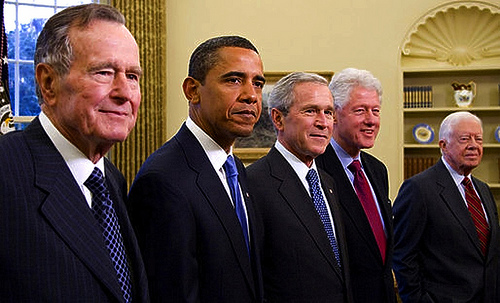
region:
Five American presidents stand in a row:
[2, 15, 467, 231]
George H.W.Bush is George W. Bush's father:
[35, 30, 125, 155]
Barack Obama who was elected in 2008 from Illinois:
[180, 30, 260, 145]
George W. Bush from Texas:
[272, 65, 342, 192]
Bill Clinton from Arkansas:
[335, 55, 385, 145]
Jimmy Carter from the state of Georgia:
[427, 101, 493, 171]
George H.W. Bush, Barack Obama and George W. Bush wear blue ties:
[45, 77, 336, 282]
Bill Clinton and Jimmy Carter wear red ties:
[337, 100, 477, 227]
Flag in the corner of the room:
[0, 58, 25, 139]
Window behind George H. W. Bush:
[3, 21, 93, 143]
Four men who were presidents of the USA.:
[13, 6, 497, 297]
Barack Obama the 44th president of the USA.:
[135, 1, 270, 297]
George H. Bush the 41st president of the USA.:
[7, 1, 148, 299]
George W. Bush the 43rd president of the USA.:
[263, 57, 338, 299]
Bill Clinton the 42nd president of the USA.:
[333, 64, 405, 301]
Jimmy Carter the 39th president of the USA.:
[411, 97, 498, 297]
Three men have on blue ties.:
[10, 0, 355, 283]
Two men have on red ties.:
[328, 50, 496, 295]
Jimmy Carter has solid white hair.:
[405, 105, 490, 300]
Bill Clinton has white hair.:
[332, 57, 392, 223]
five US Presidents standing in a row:
[30, 7, 491, 193]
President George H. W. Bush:
[37, 5, 144, 202]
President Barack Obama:
[171, 33, 278, 176]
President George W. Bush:
[270, 67, 337, 182]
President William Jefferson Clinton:
[323, 61, 388, 173]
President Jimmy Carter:
[426, 103, 499, 180]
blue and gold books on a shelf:
[400, 82, 435, 116]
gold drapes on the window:
[133, 7, 180, 142]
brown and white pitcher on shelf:
[449, 79, 481, 113]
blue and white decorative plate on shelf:
[408, 119, 435, 152]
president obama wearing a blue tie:
[161, 20, 273, 302]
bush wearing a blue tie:
[266, 62, 348, 301]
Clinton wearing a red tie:
[319, 50, 396, 301]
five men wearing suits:
[34, 12, 498, 268]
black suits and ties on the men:
[18, 163, 468, 275]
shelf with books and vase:
[402, 70, 498, 110]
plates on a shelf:
[404, 110, 499, 146]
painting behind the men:
[204, 65, 359, 162]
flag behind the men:
[0, 0, 22, 134]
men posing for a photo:
[37, 7, 498, 199]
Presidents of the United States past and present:
[5, 3, 493, 279]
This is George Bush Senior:
[30, 0, 155, 165]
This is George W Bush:
[265, 65, 335, 190]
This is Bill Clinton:
[330, 50, 390, 190]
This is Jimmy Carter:
[420, 95, 491, 255]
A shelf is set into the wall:
[400, 2, 496, 104]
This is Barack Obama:
[162, 21, 267, 216]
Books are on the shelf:
[400, 80, 436, 112]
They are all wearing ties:
[75, 152, 490, 287]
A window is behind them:
[3, 3, 63, 127]